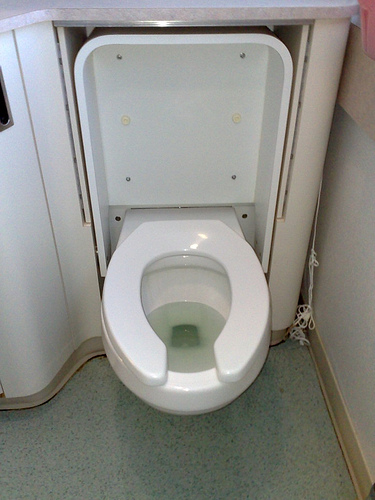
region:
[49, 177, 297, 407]
white porcelain toilet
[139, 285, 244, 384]
toilet water in the bowl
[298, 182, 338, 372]
a white cord hanging in the corner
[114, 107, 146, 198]
bolts holding the toilet the wall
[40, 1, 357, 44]
the bathroom countertop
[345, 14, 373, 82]
a red plastic container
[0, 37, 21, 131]
a metal hole in the cabinet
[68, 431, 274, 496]
the speckled bathroom floor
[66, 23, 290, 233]
the white metal toilet structure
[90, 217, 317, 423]
the white plastic toilet seat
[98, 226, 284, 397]
white toilet in bathroom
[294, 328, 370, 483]
cream molding on ground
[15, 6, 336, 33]
white marble counter top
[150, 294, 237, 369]
clear water in toliet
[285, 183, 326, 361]
white stringing hanging down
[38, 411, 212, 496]
blue foolr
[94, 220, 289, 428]
the toilet is clean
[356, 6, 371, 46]
pink box on wall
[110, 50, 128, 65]
silver screw above toilet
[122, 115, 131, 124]
white screw above toilet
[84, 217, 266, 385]
The toilet seat is white.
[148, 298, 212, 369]
Water in the toilet.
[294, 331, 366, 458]
Tan floor boards.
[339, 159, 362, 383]
The wall is white.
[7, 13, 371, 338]
This is a bathroom.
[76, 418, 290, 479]
The floor is blue.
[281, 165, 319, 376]
The string is white.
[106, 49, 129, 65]
The screws are silver.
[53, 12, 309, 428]
There is only one toilet.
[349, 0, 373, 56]
Plastic red container.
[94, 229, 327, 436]
water is in the toilet bowl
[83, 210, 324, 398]
the toilet seat is white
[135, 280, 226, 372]
a hole is in the toilet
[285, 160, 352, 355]
strings are next to the toilet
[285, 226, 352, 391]
the strings are white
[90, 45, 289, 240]
screws are on the toilet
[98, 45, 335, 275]
the screws are gray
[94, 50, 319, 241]
4 screws are on the toilet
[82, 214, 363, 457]
the toilet seat is down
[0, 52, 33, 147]
the handle is grey and black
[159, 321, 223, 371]
toilet water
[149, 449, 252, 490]
floor of bathroom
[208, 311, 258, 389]
lid of white toilet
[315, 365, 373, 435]
surface of bathroom wall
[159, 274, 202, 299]
back edge of white toilet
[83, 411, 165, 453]
dirty floor of bathroom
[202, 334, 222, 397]
middle of toilet lid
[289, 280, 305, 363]
string whose function is not known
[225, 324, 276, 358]
outer edge of toilet lid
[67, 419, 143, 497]
dirty dotted floor